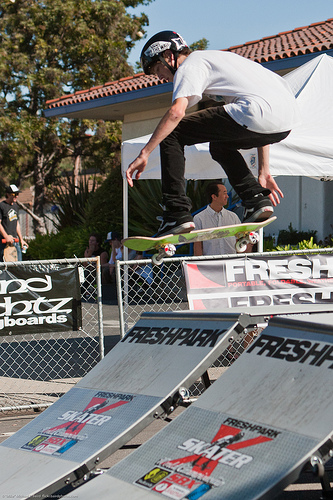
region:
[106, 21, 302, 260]
a young man on a skateboard.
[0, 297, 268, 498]
A gray skateboard ramp.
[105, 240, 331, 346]
a metal chain link fence.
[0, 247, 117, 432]
a short metal chain link fence.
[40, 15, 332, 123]
a pink roof top.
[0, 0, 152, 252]
a tall leafy green tree.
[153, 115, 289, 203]
a pair of black pants.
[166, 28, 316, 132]
a white t shirt.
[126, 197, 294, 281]
a green skateboard.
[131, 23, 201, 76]
a black and white helmet.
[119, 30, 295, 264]
a skateboarder in the air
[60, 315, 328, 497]
a metal quarter pipe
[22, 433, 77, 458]
stickers on a ramp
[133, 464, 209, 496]
stickers on a ramp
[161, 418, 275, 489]
logo on a ramp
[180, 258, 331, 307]
a black white and red sign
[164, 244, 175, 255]
a wheel on a skateboard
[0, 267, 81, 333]
black and white sign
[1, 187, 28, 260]
a man holding a skateboard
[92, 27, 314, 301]
a boy jumping a skateboard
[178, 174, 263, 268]
an Asian man smiling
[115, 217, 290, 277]
a yellow skateboard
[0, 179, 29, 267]
a man wearing a black and white cap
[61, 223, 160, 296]
a group of people sitting down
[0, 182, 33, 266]
a man wearing a black T-shirt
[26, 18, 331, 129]
the roof of a building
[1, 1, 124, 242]
a large deciduous tree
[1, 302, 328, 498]
two metal skateboard ramps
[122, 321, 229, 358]
Freshpark nameplate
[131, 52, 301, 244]
man on skateboard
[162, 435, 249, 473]
logo on the ramp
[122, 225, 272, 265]
a skateboard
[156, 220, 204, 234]
man is wearing shoes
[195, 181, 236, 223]
a man standing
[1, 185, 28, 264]
a person standing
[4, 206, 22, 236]
person wearing a black shirt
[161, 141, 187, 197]
man wearing black pants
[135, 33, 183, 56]
a helmet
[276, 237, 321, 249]
the green leaves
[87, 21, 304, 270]
a person on a skateboard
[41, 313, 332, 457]
boardskating ramps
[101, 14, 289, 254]
a guy in black pants on a skateboard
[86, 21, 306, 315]
a guy up in the air with his skateboard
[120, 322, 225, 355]
a FRESHPARK print on the ramp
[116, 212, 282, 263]
a skateboard in the air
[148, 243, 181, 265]
wheels of the skateboard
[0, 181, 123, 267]
people in the background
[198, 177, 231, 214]
an asian guy in the background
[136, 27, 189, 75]
a helmet a guy is wearing